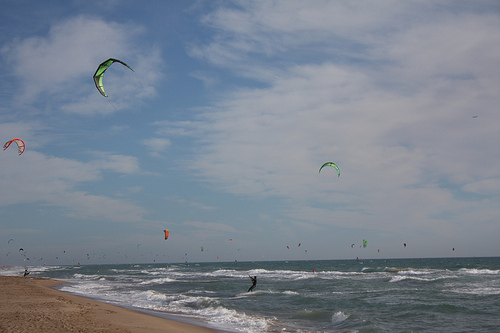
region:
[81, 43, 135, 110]
kite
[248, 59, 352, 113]
white clouds in blue sky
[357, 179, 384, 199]
white clouds in blue sky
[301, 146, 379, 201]
white clouds in blue sky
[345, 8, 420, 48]
white clouds in blue sky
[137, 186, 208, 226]
white clouds in blue sky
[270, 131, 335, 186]
white clouds in blue sky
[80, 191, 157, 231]
white clouds in blue sky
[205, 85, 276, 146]
white clouds in blue sky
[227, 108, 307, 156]
white clouds in blue sky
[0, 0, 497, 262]
partly cloudy blue sky above the ocean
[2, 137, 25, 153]
red and white windsurfing kite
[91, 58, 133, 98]
green windsurfing kite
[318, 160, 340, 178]
green windsurfing kite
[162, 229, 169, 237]
a windsurfing kite in the sky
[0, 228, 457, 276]
many windsurfing kites above the ocean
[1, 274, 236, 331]
a sandy beach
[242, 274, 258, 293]
a windsurfer in the ocean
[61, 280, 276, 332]
waves crashing on the shore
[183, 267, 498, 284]
whitecaps on ocean waves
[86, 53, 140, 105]
wind surfing sail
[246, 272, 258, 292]
man is windsurfing on the water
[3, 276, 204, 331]
sand on the beach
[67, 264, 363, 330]
light waves going toward the shore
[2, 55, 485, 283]
many people are wind surfing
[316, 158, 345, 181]
green windsurfing sail in the air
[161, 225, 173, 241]
red wind surfing sail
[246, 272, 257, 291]
silhouette of a person wind surfing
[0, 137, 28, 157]
a red and white wind surfing sail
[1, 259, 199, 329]
the beach is empty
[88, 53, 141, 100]
parachute in mid air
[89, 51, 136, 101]
parachute that is black and green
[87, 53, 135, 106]
black and green parachute in air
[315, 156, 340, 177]
blue parachute in air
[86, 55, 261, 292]
person parasurfing in ocean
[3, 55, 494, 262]
multiple people parasurfing in ocean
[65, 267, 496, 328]
white capped waves in ocean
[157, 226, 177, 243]
red parachute in mid air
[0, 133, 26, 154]
red and white parachute in mid air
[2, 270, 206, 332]
sand on beach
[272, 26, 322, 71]
white clouds in blue sky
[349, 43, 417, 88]
white clouds in blue sky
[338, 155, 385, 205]
white clouds in blue sky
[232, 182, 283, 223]
white clouds in blue sky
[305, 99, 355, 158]
white clouds in blue sky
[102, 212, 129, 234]
white clouds in blue sky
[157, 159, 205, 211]
white clouds in blue sky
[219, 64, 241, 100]
white clouds in blue sky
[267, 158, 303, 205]
white clouds in blue sky